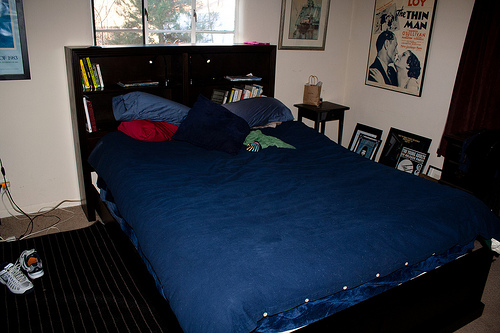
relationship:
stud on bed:
[260, 307, 272, 324] [61, 32, 499, 332]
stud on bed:
[301, 294, 313, 308] [61, 32, 499, 332]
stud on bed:
[339, 283, 352, 293] [61, 32, 499, 332]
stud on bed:
[373, 268, 383, 281] [61, 32, 499, 332]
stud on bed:
[399, 257, 416, 271] [61, 32, 499, 332]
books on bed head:
[80, 60, 264, 115] [58, 33, 285, 127]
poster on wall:
[357, 0, 445, 104] [281, 2, 453, 132]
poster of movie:
[357, 0, 445, 104] [394, 9, 433, 32]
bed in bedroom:
[61, 32, 499, 332] [2, 4, 499, 332]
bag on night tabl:
[299, 74, 328, 112] [297, 99, 352, 143]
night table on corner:
[297, 99, 352, 143] [292, 89, 366, 137]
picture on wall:
[277, 0, 335, 55] [281, 2, 453, 132]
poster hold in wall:
[357, 0, 445, 104] [281, 2, 453, 132]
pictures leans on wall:
[0, 0, 36, 83] [281, 2, 453, 132]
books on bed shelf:
[80, 60, 264, 115] [58, 33, 285, 127]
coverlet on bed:
[89, 106, 497, 312] [61, 32, 499, 332]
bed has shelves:
[61, 32, 499, 332] [58, 33, 285, 127]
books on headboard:
[80, 60, 264, 115] [56, 37, 285, 219]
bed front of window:
[61, 32, 499, 332] [89, 2, 246, 47]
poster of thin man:
[357, 0, 445, 104] [394, 9, 433, 32]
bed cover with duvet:
[61, 32, 499, 332] [89, 106, 497, 312]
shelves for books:
[58, 33, 285, 127] [80, 60, 264, 115]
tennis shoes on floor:
[1, 242, 51, 304] [3, 223, 149, 333]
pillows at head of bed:
[104, 84, 300, 156] [56, 37, 285, 219]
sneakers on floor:
[1, 242, 51, 304] [3, 223, 149, 333]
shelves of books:
[56, 37, 285, 219] [80, 60, 264, 115]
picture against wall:
[277, 0, 335, 55] [281, 2, 453, 132]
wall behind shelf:
[22, 4, 280, 47] [58, 33, 285, 127]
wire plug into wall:
[5, 178, 78, 223] [0, 112, 72, 217]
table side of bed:
[297, 99, 352, 143] [61, 32, 499, 332]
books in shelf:
[80, 60, 264, 115] [56, 37, 285, 219]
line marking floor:
[86, 223, 145, 331] [3, 223, 149, 333]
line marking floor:
[45, 232, 79, 331] [3, 223, 149, 333]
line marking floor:
[61, 231, 101, 331] [3, 223, 149, 333]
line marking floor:
[94, 223, 164, 331] [3, 223, 149, 333]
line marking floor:
[29, 292, 45, 331] [3, 223, 149, 333]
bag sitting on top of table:
[299, 74, 328, 112] [292, 99, 352, 146]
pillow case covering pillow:
[109, 89, 191, 128] [104, 88, 192, 123]